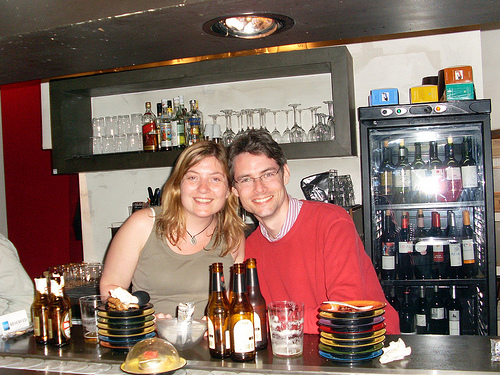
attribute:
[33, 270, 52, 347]
bottle — of beer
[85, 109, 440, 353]
people — close together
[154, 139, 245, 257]
hair — long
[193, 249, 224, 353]
bottle — beer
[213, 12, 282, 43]
light — round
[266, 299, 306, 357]
glass — empty beer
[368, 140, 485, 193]
bottles — wine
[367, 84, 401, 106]
box — blue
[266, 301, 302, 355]
glass — clear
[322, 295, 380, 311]
spoon — plastic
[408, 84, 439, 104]
box — yellow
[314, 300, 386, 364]
stack — colorful